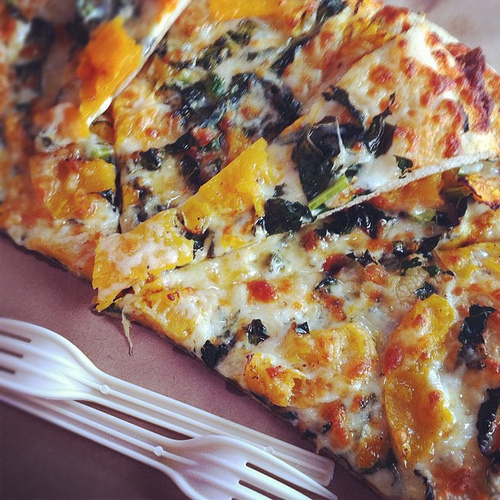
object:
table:
[0, 0, 500, 500]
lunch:
[1, 0, 499, 498]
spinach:
[249, 393, 292, 422]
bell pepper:
[175, 136, 278, 233]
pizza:
[0, 0, 500, 500]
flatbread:
[90, 18, 500, 313]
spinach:
[70, 0, 119, 31]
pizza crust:
[427, 44, 497, 155]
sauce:
[246, 277, 278, 301]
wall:
[200, 113, 252, 160]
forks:
[0, 393, 339, 500]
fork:
[0, 316, 335, 489]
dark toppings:
[291, 115, 363, 202]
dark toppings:
[229, 72, 299, 143]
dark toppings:
[201, 319, 271, 370]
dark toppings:
[458, 305, 496, 370]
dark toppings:
[263, 197, 314, 235]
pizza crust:
[365, 3, 407, 50]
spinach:
[165, 18, 264, 120]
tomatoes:
[316, 398, 350, 453]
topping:
[181, 135, 279, 240]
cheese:
[188, 0, 299, 134]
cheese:
[143, 237, 330, 356]